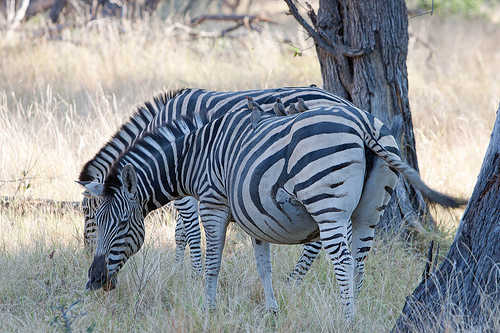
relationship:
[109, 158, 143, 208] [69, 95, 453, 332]
ear on zebra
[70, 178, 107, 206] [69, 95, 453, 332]
ear on zebra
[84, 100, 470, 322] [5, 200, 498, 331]
zebra eating some grass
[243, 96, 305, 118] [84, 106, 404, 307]
birds on zebra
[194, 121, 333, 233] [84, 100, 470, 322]
stripes on zebra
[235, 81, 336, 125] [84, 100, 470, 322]
birds are on zebra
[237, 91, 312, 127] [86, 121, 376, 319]
birds perched on back of zebra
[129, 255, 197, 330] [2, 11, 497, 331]
grass in field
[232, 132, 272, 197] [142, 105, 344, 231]
stripes on a zebras coat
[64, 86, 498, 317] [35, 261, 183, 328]
zebras grazing on yellow grass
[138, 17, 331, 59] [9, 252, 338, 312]
branches in grass